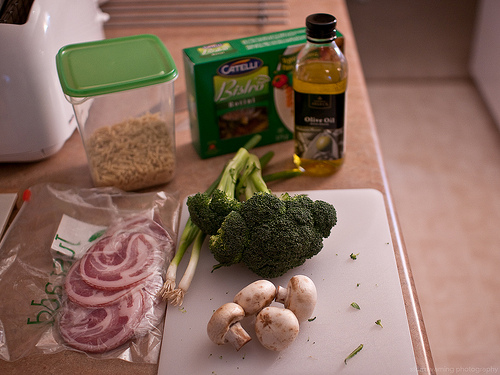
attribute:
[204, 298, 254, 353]
mushroom — white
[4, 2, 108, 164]
toaster — white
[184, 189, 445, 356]
board — white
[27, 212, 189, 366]
baf — clear, plastic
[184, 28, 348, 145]
box — green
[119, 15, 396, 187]
box — Catelli Bistro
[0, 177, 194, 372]
bag — plastic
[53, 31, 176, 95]
lid — green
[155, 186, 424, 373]
cutting board — plastic, white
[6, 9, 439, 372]
counter — wooden